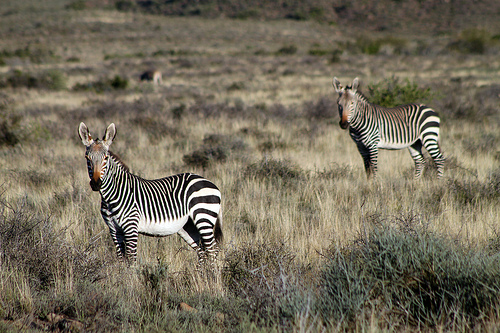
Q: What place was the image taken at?
A: It was taken at the field.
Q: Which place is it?
A: It is a field.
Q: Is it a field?
A: Yes, it is a field.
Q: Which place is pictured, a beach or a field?
A: It is a field.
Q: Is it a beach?
A: No, it is a field.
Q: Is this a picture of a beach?
A: No, the picture is showing a field.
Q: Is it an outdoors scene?
A: Yes, it is outdoors.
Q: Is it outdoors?
A: Yes, it is outdoors.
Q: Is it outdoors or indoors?
A: It is outdoors.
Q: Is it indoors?
A: No, it is outdoors.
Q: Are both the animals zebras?
A: Yes, all the animals are zebras.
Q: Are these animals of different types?
A: No, all the animals are zebras.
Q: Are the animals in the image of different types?
A: No, all the animals are zebras.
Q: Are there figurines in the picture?
A: No, there are no figurines.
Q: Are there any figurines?
A: No, there are no figurines.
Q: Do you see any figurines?
A: No, there are no figurines.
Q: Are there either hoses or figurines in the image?
A: No, there are no figurines or hoses.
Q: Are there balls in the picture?
A: No, there are no balls.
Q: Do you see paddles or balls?
A: No, there are no balls or paddles.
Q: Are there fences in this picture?
A: No, there are no fences.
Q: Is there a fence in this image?
A: No, there are no fences.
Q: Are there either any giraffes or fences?
A: No, there are no fences or giraffes.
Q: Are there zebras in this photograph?
A: Yes, there is a zebra.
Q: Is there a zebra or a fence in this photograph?
A: Yes, there is a zebra.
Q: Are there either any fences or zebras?
A: Yes, there is a zebra.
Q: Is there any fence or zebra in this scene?
A: Yes, there is a zebra.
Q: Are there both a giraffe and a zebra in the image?
A: No, there is a zebra but no giraffes.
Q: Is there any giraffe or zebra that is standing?
A: Yes, the zebra is standing.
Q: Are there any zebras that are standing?
A: Yes, there is a zebra that is standing.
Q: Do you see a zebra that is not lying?
A: Yes, there is a zebra that is standing .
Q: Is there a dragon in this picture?
A: No, there are no dragons.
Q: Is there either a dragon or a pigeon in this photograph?
A: No, there are no dragons or pigeons.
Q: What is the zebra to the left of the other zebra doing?
A: The zebra is standing.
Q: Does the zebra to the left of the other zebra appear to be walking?
A: No, the zebra is standing.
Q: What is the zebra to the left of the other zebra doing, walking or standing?
A: The zebra is standing.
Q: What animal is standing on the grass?
A: The zebra is standing on the grass.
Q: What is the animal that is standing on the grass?
A: The animal is a zebra.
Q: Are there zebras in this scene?
A: Yes, there is a zebra.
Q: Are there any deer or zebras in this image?
A: Yes, there is a zebra.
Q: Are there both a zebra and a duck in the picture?
A: No, there is a zebra but no ducks.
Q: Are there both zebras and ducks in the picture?
A: No, there is a zebra but no ducks.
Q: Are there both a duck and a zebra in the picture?
A: No, there is a zebra but no ducks.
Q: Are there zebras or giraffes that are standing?
A: Yes, the zebra is standing.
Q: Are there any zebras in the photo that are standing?
A: Yes, there is a zebra that is standing.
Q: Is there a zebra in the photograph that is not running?
A: Yes, there is a zebra that is standing.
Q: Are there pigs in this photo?
A: No, there are no pigs.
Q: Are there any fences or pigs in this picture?
A: No, there are no pigs or fences.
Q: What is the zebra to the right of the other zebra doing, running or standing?
A: The zebra is standing.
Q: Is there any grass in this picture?
A: Yes, there is grass.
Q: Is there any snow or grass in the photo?
A: Yes, there is grass.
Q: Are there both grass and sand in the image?
A: No, there is grass but no sand.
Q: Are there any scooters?
A: No, there are no scooters.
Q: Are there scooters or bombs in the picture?
A: No, there are no scooters or bombs.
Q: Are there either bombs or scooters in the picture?
A: No, there are no scooters or bombs.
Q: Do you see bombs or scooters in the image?
A: No, there are no scooters or bombs.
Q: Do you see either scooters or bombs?
A: No, there are no scooters or bombs.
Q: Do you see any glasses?
A: No, there are no glasses.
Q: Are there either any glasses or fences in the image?
A: No, there are no glasses or fences.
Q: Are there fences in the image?
A: No, there are no fences.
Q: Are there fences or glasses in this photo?
A: No, there are no fences or glasses.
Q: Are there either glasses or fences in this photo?
A: No, there are no fences or glasses.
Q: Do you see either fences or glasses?
A: No, there are no fences or glasses.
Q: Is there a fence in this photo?
A: No, there are no fences.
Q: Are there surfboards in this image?
A: No, there are no surfboards.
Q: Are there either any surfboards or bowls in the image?
A: No, there are no surfboards or bowls.